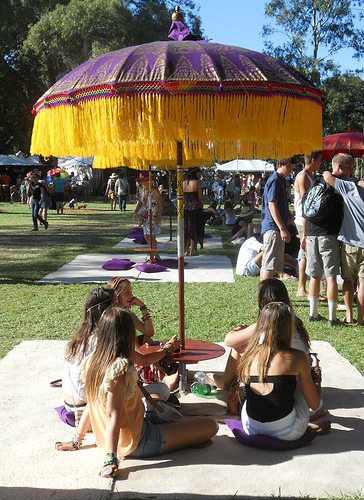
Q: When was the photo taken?
A: Daytime.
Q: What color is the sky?
A: Blue.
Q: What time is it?
A: Daytime.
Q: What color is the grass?
A: Green.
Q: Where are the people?
A: At a park.